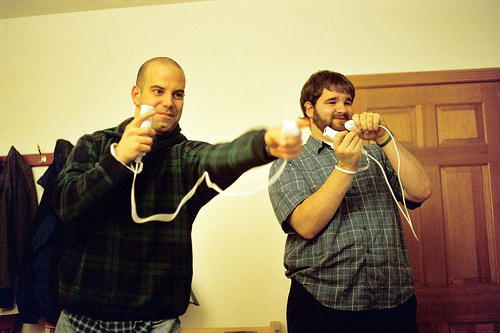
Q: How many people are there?
A: Two.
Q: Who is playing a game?
A: A man.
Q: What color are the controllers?
A: White.